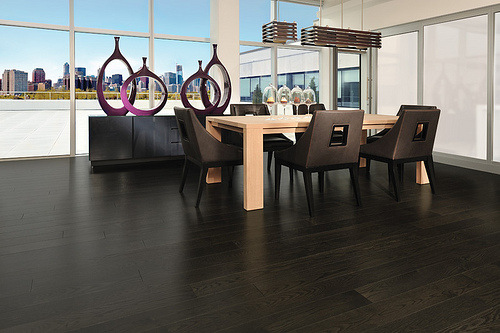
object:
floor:
[0, 158, 500, 332]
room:
[0, 1, 499, 333]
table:
[203, 113, 435, 212]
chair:
[268, 109, 366, 222]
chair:
[358, 111, 442, 204]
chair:
[171, 105, 250, 207]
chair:
[228, 103, 296, 192]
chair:
[369, 105, 439, 182]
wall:
[318, 0, 496, 30]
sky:
[0, 0, 321, 92]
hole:
[327, 124, 350, 150]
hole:
[411, 120, 429, 144]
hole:
[178, 119, 192, 143]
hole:
[245, 110, 257, 116]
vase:
[95, 35, 140, 117]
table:
[85, 113, 247, 174]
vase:
[119, 55, 170, 115]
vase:
[178, 58, 223, 113]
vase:
[197, 44, 233, 115]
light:
[261, 21, 299, 46]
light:
[300, 27, 383, 53]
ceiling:
[290, 1, 387, 9]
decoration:
[261, 81, 279, 116]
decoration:
[276, 82, 293, 117]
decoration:
[291, 81, 305, 117]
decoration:
[301, 85, 317, 115]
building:
[1, 67, 31, 95]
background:
[0, 0, 499, 332]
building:
[30, 66, 46, 91]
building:
[63, 60, 71, 89]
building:
[175, 62, 185, 92]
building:
[161, 72, 181, 95]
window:
[151, 38, 214, 115]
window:
[74, 31, 151, 155]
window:
[0, 23, 73, 160]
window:
[151, 0, 218, 40]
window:
[73, 1, 152, 33]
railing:
[2, 87, 211, 99]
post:
[69, 31, 77, 155]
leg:
[240, 130, 263, 212]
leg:
[194, 167, 208, 214]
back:
[310, 114, 366, 166]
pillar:
[208, 0, 241, 116]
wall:
[0, 1, 322, 161]